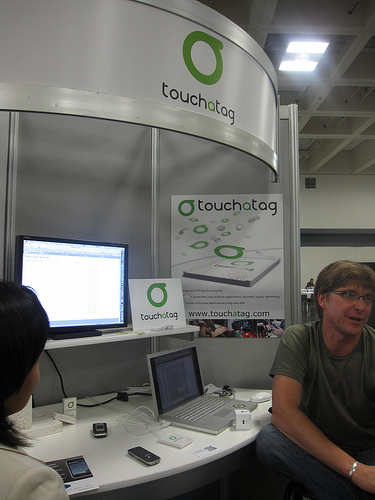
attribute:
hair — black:
[0, 278, 49, 449]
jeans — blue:
[254, 423, 358, 499]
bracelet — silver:
[348, 461, 358, 480]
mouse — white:
[242, 379, 272, 407]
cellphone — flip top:
[89, 419, 112, 438]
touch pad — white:
[154, 429, 192, 451]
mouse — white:
[246, 381, 279, 416]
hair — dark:
[5, 279, 44, 376]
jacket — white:
[3, 436, 66, 491]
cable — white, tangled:
[114, 404, 172, 437]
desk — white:
[66, 423, 217, 496]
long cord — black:
[41, 348, 68, 399]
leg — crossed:
[258, 423, 372, 499]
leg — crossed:
[285, 460, 332, 499]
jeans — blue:
[259, 429, 342, 498]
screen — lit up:
[15, 230, 132, 326]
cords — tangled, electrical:
[126, 402, 160, 442]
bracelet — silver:
[346, 446, 369, 496]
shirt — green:
[263, 317, 363, 443]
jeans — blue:
[247, 418, 356, 492]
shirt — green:
[269, 318, 373, 444]